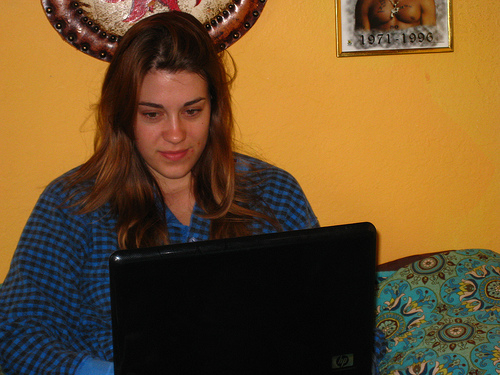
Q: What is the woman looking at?
A: Laptop.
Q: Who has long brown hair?
A: The woman.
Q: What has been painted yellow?
A: The wall.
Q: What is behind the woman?
A: Yellow wall.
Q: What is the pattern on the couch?
A: Floral.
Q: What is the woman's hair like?
A: Long.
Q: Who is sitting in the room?
A: The woman.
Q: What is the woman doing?
A: Looking at the laptop.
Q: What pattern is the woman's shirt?
A: Plaid.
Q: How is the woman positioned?
A: Sitting.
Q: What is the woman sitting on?
A: A bed.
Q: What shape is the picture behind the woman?
A: Round.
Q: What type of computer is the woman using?
A: A laptop.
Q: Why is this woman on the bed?
A: To use the laptop.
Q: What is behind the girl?
A: A plate on the wall.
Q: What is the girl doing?
A: Looking at the computer.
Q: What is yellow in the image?
A: The wall.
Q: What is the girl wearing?
A: A blue flannel shirt.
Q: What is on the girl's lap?
A: A laptop.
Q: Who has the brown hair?
A: The woman.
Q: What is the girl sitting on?
A: The couch.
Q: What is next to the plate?
A: A picture on the wall.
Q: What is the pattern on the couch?
A: Paisley.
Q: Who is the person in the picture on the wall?
A: Tupac.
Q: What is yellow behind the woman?
A: Wall.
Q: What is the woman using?
A: Laptop.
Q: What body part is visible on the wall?
A: Chest.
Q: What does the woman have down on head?
A: Hair.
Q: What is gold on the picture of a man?
A: Frame.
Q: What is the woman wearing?
A: Shirt.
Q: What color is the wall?
A: Yellow.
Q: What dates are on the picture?
A: 1971-1990.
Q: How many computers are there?
A: One.